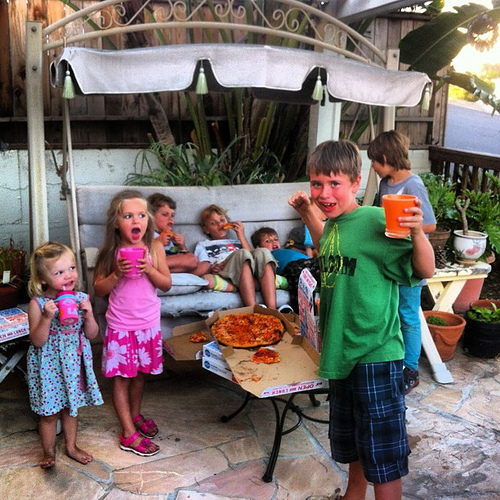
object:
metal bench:
[23, 0, 436, 347]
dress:
[26, 290, 104, 418]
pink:
[104, 271, 161, 333]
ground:
[0, 349, 499, 499]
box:
[162, 304, 330, 399]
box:
[297, 268, 320, 354]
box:
[0, 305, 35, 344]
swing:
[23, 0, 435, 353]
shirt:
[317, 205, 428, 381]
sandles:
[119, 411, 160, 457]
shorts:
[101, 325, 164, 378]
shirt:
[104, 245, 161, 331]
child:
[88, 190, 174, 459]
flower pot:
[452, 230, 488, 265]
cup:
[119, 247, 144, 280]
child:
[25, 240, 99, 469]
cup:
[54, 284, 82, 325]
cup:
[382, 194, 418, 240]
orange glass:
[381, 194, 418, 240]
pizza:
[190, 313, 285, 365]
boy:
[194, 204, 278, 311]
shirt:
[195, 238, 243, 264]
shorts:
[325, 359, 413, 483]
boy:
[287, 140, 434, 499]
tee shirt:
[315, 203, 426, 380]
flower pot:
[420, 310, 467, 362]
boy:
[250, 226, 322, 315]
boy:
[142, 192, 210, 277]